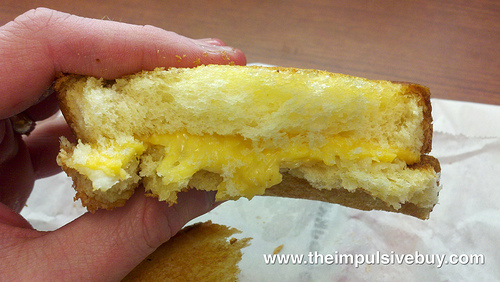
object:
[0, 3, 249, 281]
hand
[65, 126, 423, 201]
melted cheese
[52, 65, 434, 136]
bread top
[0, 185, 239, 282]
thumb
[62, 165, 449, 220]
lower bread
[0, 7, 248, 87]
index finger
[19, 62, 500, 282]
white surface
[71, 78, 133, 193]
piece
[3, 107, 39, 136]
ring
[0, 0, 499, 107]
table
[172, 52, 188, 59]
crumbs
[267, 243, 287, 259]
crumbs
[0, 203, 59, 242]
folds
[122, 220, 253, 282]
bread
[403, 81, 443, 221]
crust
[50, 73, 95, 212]
crust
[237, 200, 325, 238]
oil stains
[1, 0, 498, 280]
indoor kitchen scene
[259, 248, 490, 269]
writing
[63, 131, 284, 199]
scrambled egg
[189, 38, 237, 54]
nails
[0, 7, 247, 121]
fingers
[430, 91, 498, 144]
edge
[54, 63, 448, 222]
sandwich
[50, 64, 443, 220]
bread